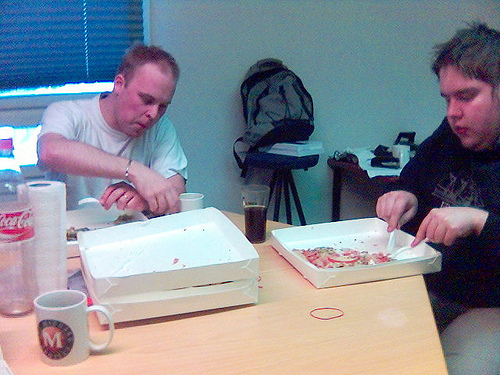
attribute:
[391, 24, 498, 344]
man — eating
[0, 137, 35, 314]
bottle — empty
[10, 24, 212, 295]
man — holding